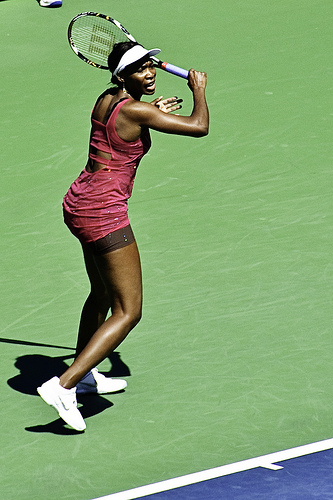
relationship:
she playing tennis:
[35, 38, 212, 436] [6, 5, 237, 465]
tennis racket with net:
[67, 12, 207, 88] [67, 16, 122, 70]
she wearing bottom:
[35, 38, 212, 436] [80, 223, 135, 256]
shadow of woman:
[0, 320, 133, 437] [81, 47, 224, 243]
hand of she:
[186, 63, 226, 89] [35, 38, 212, 436]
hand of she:
[149, 90, 185, 114] [35, 38, 212, 436]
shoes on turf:
[22, 340, 146, 445] [2, 1, 322, 496]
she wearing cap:
[12, 33, 219, 437] [111, 44, 162, 81]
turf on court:
[7, 45, 331, 445] [0, 1, 320, 498]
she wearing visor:
[35, 38, 212, 436] [111, 45, 159, 76]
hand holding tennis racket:
[186, 66, 209, 93] [63, 9, 192, 82]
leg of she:
[58, 242, 143, 389] [35, 38, 212, 436]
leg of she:
[72, 250, 112, 359] [35, 38, 212, 436]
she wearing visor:
[35, 38, 212, 436] [108, 36, 163, 80]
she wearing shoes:
[35, 38, 212, 436] [34, 375, 90, 436]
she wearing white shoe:
[35, 38, 212, 436] [75, 366, 127, 394]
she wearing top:
[35, 38, 212, 436] [57, 84, 154, 242]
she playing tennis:
[35, 38, 212, 436] [61, 7, 208, 85]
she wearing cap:
[35, 38, 212, 436] [112, 44, 161, 74]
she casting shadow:
[35, 38, 212, 436] [0, 334, 129, 435]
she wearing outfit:
[35, 38, 212, 436] [58, 76, 152, 257]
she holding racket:
[35, 38, 212, 436] [63, 10, 222, 101]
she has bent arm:
[35, 38, 212, 436] [145, 69, 214, 139]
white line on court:
[87, 439, 331, 498] [0, 1, 333, 500]